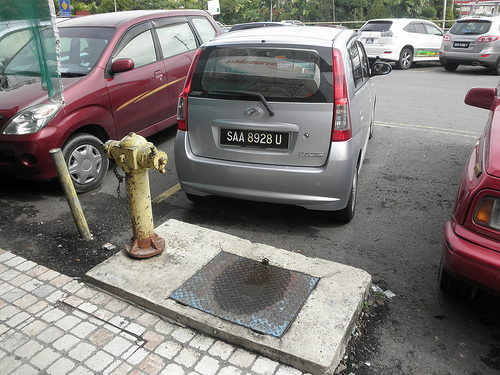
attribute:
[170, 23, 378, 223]
minivan — parked, silver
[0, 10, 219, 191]
van — parked, red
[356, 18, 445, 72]
car — parked, white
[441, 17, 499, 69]
car — parked, silver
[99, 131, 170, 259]
hydrant — rusty, yellow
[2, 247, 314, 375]
sidewalk — stone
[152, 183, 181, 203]
line — yellow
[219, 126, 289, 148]
license plate — black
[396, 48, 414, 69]
tire — black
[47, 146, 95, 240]
pole — yellow, metal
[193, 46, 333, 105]
windshield — black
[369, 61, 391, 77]
side mirror — black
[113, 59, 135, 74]
mirror — red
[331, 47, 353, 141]
tail lights — present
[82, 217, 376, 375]
square — concrete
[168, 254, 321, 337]
cover — metal, square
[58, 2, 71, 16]
sign — blue